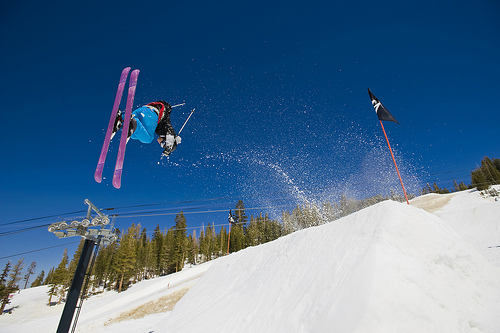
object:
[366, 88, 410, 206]
flag pole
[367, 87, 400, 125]
flag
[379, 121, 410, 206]
pole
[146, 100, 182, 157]
black jacket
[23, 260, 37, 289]
tree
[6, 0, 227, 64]
sky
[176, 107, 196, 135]
ski poles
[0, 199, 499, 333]
snow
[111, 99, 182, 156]
person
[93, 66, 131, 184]
ski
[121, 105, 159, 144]
pants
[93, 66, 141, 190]
skis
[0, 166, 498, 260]
cables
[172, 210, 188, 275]
tree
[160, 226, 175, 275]
tree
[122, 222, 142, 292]
tree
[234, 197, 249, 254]
tree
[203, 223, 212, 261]
tree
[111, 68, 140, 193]
ski